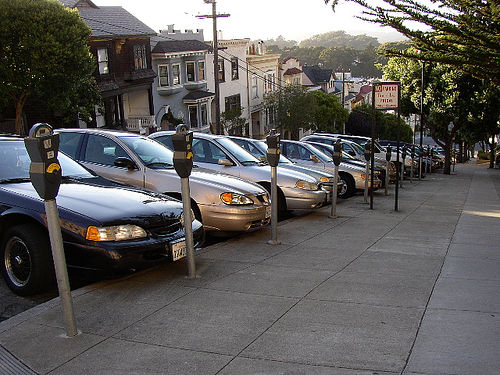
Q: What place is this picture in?
A: It is at the sidewalk.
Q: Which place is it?
A: It is a sidewalk.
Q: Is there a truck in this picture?
A: No, there are no trucks.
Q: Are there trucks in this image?
A: No, there are no trucks.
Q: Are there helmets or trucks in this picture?
A: No, there are no trucks or helmets.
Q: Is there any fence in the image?
A: No, there are no fences.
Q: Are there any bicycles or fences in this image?
A: No, there are no fences or bicycles.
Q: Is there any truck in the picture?
A: No, there are no trucks.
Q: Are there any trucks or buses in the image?
A: No, there are no trucks or buses.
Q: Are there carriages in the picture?
A: No, there are no carriages.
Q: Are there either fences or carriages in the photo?
A: No, there are no carriages or fences.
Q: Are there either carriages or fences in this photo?
A: No, there are no carriages or fences.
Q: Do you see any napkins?
A: No, there are no napkins.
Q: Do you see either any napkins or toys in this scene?
A: No, there are no napkins or toys.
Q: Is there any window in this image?
A: Yes, there is a window.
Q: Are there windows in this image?
A: Yes, there is a window.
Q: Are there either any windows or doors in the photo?
A: Yes, there is a window.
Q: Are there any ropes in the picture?
A: No, there are no ropes.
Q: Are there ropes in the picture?
A: No, there are no ropes.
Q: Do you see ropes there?
A: No, there are no ropes.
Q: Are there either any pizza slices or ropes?
A: No, there are no ropes or pizza slices.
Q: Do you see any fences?
A: No, there are no fences.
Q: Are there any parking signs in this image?
A: Yes, there is a parking sign.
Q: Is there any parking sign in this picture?
A: Yes, there is a parking sign.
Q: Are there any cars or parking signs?
A: Yes, there is a parking sign.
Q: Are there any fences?
A: No, there are no fences.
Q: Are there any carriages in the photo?
A: No, there are no carriages.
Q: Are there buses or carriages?
A: No, there are no carriages or buses.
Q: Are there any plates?
A: Yes, there is a plate.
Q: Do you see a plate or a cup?
A: Yes, there is a plate.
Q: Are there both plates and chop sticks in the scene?
A: No, there is a plate but no chopsticks.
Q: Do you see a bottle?
A: No, there are no bottles.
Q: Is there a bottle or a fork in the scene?
A: No, there are no bottles or forks.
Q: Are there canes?
A: No, there are no canes.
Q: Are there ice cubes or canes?
A: No, there are no canes or ice cubes.